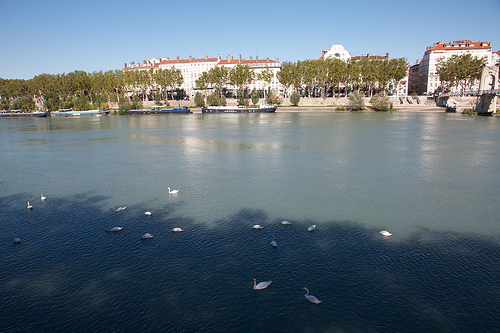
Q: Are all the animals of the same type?
A: Yes, all the animals are birds.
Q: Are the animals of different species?
A: No, all the animals are birds.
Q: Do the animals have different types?
A: No, all the animals are birds.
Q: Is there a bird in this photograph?
A: Yes, there is a bird.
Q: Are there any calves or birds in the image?
A: Yes, there is a bird.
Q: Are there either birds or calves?
A: Yes, there is a bird.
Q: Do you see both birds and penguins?
A: No, there is a bird but no penguins.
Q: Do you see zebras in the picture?
A: No, there are no zebras.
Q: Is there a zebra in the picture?
A: No, there are no zebras.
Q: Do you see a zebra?
A: No, there are no zebras.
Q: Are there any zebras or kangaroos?
A: No, there are no zebras or kangaroos.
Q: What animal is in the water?
A: The bird is in the water.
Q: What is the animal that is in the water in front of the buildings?
A: The animal is a bird.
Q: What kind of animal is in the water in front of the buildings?
A: The animal is a bird.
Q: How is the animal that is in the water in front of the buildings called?
A: The animal is a bird.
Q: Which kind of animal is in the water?
A: The animal is a bird.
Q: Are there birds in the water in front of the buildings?
A: Yes, there is a bird in the water.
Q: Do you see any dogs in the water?
A: No, there is a bird in the water.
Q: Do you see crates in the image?
A: No, there are no crates.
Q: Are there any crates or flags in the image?
A: No, there are no crates or flags.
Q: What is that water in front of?
A: The water is in front of the buildings.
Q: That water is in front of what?
A: The water is in front of the buildings.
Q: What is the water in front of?
A: The water is in front of the buildings.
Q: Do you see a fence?
A: No, there are no fences.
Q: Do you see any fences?
A: No, there are no fences.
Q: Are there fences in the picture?
A: No, there are no fences.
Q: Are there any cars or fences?
A: No, there are no fences or cars.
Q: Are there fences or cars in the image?
A: No, there are no fences or cars.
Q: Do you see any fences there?
A: No, there are no fences.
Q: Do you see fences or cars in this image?
A: No, there are no fences or cars.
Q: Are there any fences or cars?
A: No, there are no fences or cars.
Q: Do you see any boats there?
A: Yes, there is a boat.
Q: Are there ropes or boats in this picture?
A: Yes, there is a boat.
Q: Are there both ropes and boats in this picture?
A: No, there is a boat but no ropes.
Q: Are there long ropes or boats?
A: Yes, there is a long boat.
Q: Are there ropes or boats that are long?
A: Yes, the boat is long.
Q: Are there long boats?
A: Yes, there is a long boat.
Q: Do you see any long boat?
A: Yes, there is a long boat.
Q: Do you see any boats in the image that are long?
A: Yes, there is a boat that is long.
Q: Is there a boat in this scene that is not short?
A: Yes, there is a long boat.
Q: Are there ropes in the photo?
A: No, there are no ropes.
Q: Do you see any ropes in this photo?
A: No, there are no ropes.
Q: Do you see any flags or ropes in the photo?
A: No, there are no ropes or flags.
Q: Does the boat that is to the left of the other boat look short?
A: No, the boat is long.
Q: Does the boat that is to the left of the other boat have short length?
A: No, the boat is long.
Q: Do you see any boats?
A: Yes, there is a boat.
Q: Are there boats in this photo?
A: Yes, there is a boat.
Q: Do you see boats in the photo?
A: Yes, there is a boat.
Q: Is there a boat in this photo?
A: Yes, there is a boat.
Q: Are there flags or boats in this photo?
A: Yes, there is a boat.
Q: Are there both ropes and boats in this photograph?
A: No, there is a boat but no ropes.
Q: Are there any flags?
A: No, there are no flags.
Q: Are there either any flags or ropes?
A: No, there are no flags or ropes.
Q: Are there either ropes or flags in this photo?
A: No, there are no flags or ropes.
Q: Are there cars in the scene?
A: No, there are no cars.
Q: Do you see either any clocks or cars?
A: No, there are no cars or clocks.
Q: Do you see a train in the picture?
A: No, there are no trains.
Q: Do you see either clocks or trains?
A: No, there are no trains or clocks.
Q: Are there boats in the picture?
A: Yes, there is a boat.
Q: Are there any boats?
A: Yes, there is a boat.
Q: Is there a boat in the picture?
A: Yes, there is a boat.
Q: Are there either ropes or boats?
A: Yes, there is a boat.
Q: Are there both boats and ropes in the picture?
A: No, there is a boat but no ropes.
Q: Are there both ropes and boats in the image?
A: No, there is a boat but no ropes.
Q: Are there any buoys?
A: No, there are no buoys.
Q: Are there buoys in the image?
A: No, there are no buoys.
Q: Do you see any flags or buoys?
A: No, there are no buoys or flags.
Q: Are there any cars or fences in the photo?
A: No, there are no cars or fences.